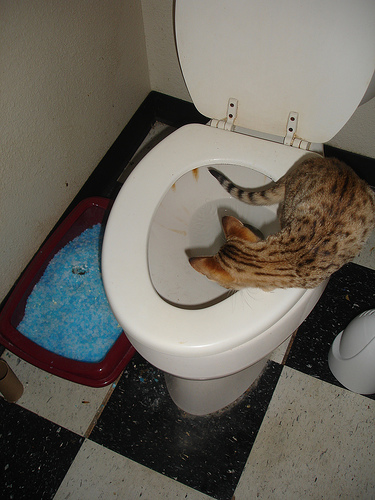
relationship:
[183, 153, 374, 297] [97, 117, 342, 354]
cat on seat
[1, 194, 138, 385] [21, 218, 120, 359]
box with sand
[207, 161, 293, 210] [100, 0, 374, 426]
tail in toilet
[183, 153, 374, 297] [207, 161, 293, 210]
cat has tail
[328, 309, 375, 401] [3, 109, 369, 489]
brush on floor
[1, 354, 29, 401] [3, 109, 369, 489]
roll on floor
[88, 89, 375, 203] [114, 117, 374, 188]
molding on edge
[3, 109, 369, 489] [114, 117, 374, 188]
floor has edge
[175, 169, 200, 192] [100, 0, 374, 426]
stain inside toilet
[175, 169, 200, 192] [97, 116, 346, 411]
stain inside bowl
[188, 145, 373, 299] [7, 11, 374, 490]
animal in photo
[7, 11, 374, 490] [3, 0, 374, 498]
photo inside room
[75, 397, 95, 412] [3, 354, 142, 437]
spot on tile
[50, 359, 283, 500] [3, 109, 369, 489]
tile on floor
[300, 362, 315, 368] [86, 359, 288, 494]
spot on tile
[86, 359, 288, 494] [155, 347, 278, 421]
tile around base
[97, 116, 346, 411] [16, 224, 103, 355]
bowl holding litter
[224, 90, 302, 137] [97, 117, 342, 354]
screws in seat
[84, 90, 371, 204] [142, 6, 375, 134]
edge at end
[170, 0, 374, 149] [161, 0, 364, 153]
wall has end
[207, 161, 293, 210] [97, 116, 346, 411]
tail in bowl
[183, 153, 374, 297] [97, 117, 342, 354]
cat laying on seat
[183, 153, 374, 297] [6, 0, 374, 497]
cat inside bathroom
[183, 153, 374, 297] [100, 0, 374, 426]
cat on toilet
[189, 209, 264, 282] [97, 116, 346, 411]
head inside bowl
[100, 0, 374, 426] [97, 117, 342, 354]
toilet with seat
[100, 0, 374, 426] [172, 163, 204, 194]
toilet with rust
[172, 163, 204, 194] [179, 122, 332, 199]
rust in far rear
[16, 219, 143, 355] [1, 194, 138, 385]
liter inside container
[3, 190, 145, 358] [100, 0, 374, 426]
container next to toilet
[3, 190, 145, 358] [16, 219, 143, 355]
container has liter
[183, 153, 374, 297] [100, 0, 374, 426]
cat looking in toilet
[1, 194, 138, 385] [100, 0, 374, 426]
box under toilet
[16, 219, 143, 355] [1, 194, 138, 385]
liter in box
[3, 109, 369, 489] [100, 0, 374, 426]
floor under toilet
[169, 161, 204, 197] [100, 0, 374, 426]
stains in toilet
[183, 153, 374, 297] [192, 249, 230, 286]
cat has ear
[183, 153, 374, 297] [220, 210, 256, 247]
cat has ear